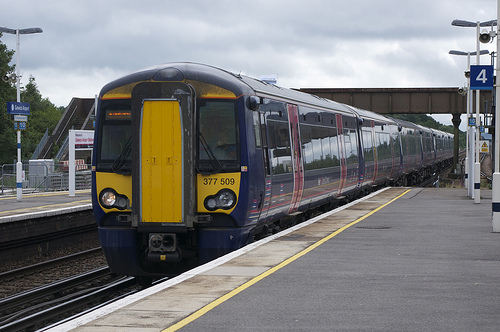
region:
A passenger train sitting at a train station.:
[83, 44, 461, 270]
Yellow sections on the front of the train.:
[91, 70, 255, 231]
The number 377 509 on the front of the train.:
[191, 165, 241, 188]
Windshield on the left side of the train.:
[98, 90, 135, 172]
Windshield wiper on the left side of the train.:
[96, 109, 134, 169]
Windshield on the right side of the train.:
[195, 91, 245, 177]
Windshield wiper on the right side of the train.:
[195, 94, 242, 169]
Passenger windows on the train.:
[261, 95, 460, 185]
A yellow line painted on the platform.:
[172, 187, 427, 328]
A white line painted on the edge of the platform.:
[45, 175, 412, 325]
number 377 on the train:
[199, 175, 220, 187]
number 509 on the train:
[219, 175, 238, 187]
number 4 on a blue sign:
[468, 65, 493, 90]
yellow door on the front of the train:
[137, 95, 188, 227]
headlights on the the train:
[96, 185, 241, 213]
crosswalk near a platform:
[27, 84, 494, 181]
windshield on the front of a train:
[91, 92, 247, 181]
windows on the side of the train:
[258, 107, 457, 178]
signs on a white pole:
[5, 93, 32, 136]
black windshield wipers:
[110, 128, 225, 179]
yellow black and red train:
[94, 59, 419, 227]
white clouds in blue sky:
[332, 13, 379, 45]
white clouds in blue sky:
[390, 22, 420, 50]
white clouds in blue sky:
[321, 31, 372, 71]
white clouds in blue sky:
[278, 16, 323, 33]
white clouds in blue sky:
[208, 16, 266, 60]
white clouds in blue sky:
[114, 2, 162, 42]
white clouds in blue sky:
[222, 33, 246, 48]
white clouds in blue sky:
[91, 33, 145, 87]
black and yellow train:
[85, 86, 423, 208]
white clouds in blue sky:
[54, 19, 81, 31]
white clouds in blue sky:
[354, 12, 392, 39]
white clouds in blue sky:
[355, 39, 402, 80]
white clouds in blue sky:
[282, 22, 330, 52]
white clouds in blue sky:
[210, 6, 254, 38]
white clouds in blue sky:
[132, 16, 186, 48]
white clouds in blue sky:
[72, 12, 133, 43]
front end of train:
[85, 47, 253, 252]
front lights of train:
[81, 178, 238, 225]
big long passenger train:
[72, 55, 453, 270]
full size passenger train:
[64, 56, 459, 266]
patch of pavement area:
[316, 256, 424, 303]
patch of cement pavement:
[334, 248, 467, 314]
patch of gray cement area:
[335, 245, 474, 316]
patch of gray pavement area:
[347, 241, 477, 317]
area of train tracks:
[45, 245, 110, 307]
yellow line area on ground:
[266, 253, 308, 277]